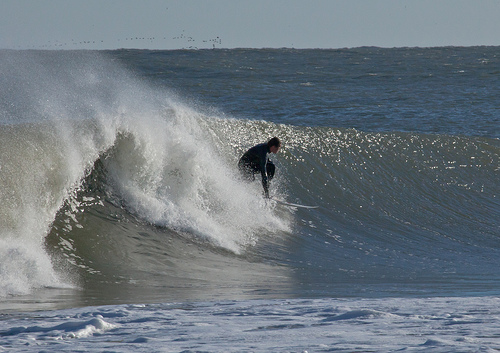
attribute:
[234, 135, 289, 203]
surfer — in water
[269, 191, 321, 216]
surfboard — white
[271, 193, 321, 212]
surfboard — in water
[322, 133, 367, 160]
ripples — the ocean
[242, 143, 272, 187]
surfing outfit — black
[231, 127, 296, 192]
surfer — in water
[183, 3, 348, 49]
blue skies — crystal blue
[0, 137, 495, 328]
wave — in water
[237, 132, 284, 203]
man — in water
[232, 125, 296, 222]
surfer — surfing, practicing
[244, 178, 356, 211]
surf board — white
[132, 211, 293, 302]
ripples — the ocean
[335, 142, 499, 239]
water — the ocean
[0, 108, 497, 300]
wave — large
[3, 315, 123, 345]
wave — foamy, small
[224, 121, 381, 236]
surfer — in water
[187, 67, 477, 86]
wave — distant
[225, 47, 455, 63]
wave — distant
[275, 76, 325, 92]
wave — little, choppy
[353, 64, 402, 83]
wave — little, choppy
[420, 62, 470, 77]
wave — little, choppy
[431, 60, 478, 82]
wave — little, choppy